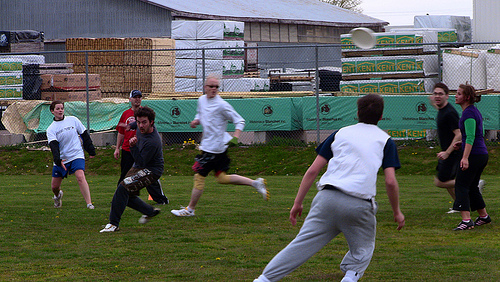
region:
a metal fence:
[32, 37, 497, 113]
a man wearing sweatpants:
[273, 69, 381, 279]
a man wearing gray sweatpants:
[229, 73, 397, 280]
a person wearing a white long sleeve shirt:
[151, 56, 265, 166]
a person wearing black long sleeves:
[27, 81, 119, 216]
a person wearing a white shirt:
[33, 93, 113, 161]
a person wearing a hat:
[108, 80, 158, 117]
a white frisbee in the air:
[302, 0, 389, 87]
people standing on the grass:
[17, 64, 444, 232]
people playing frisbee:
[31, 9, 488, 256]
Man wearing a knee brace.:
[189, 170, 211, 198]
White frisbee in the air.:
[345, 18, 387, 57]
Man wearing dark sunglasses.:
[198, 72, 233, 97]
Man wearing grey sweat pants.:
[229, 188, 391, 280]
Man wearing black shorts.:
[187, 138, 228, 179]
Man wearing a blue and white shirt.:
[315, 91, 397, 203]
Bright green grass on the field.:
[123, 219, 251, 275]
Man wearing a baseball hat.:
[121, 83, 151, 103]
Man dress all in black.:
[425, 73, 452, 210]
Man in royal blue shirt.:
[44, 148, 89, 188]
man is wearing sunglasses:
[168, 74, 271, 220]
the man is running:
[168, 74, 273, 217]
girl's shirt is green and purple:
[448, 82, 493, 232]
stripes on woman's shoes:
[455, 217, 486, 237]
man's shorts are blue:
[49, 156, 86, 180]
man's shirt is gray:
[127, 129, 164, 179]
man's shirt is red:
[113, 109, 140, 151]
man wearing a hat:
[128, 87, 145, 99]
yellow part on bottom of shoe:
[263, 178, 271, 201]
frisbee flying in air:
[338, 26, 390, 61]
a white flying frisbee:
[346, 25, 376, 50]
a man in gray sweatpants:
[250, 90, 401, 275]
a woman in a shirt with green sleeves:
[447, 80, 487, 230]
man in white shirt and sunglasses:
[167, 72, 267, 213]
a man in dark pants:
[97, 105, 162, 230]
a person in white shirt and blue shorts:
[45, 95, 95, 205]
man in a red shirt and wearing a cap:
[110, 85, 140, 195]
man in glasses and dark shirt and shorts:
[421, 80, 481, 215]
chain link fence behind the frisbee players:
[0, 40, 495, 146]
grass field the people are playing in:
[0, 173, 497, 278]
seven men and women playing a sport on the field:
[45, 72, 495, 277]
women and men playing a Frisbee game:
[45, 73, 490, 278]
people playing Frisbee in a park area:
[44, 73, 493, 280]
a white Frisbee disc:
[351, 25, 376, 49]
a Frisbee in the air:
[347, 25, 376, 49]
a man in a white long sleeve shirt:
[170, 75, 270, 219]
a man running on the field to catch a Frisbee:
[170, 75, 272, 215]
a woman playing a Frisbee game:
[450, 83, 493, 233]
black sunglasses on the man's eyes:
[205, 80, 220, 89]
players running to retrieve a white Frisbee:
[43, 25, 406, 280]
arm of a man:
[48, 121, 65, 171]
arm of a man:
[75, 119, 95, 156]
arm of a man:
[112, 116, 123, 151]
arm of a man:
[220, 101, 246, 141]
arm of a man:
[288, 131, 339, 219]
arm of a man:
[382, 140, 401, 227]